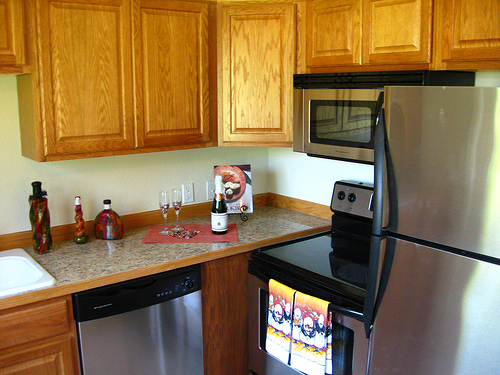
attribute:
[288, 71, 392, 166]
microwave — steel, black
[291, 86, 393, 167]
steel — stainless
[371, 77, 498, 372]
fridge — steel, stainless, silver, black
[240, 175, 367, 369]
stove — steel, black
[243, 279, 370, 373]
steel — stainless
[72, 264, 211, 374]
dishwasher — steel, black, silver, shiny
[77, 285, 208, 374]
steel — stainless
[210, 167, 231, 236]
wine — unopened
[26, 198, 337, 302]
counter — granite, brown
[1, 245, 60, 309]
sink — white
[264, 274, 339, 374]
towels — hanging, colorful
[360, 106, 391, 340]
handles — black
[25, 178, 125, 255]
bottles — decorative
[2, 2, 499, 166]
cabinets — wooden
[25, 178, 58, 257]
bottle — swirly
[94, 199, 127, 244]
jar — sealed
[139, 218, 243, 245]
placemat — red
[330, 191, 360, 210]
knobs — black